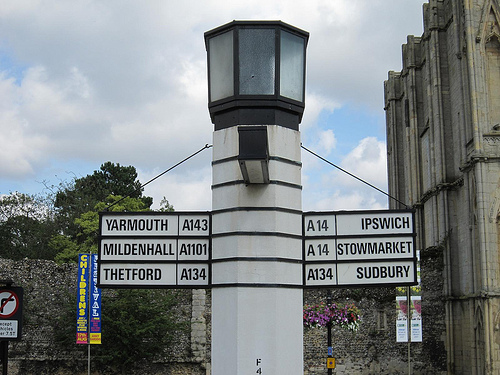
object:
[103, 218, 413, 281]
letters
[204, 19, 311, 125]
light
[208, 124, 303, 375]
post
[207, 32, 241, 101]
panes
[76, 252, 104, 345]
banner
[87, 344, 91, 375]
pole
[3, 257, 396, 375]
wall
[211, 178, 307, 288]
stripes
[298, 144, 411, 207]
cable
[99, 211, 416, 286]
sign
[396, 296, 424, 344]
banner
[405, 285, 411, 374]
pole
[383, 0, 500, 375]
building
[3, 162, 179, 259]
trees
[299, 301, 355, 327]
flowers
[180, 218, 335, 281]
numbers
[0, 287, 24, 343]
traffic sign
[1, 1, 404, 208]
clouds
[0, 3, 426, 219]
sky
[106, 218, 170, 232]
yarmouth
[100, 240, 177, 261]
mildenhall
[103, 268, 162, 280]
thetford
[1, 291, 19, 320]
no right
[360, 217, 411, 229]
ipswich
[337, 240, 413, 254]
stowmarket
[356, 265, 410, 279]
sudbury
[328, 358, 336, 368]
sign